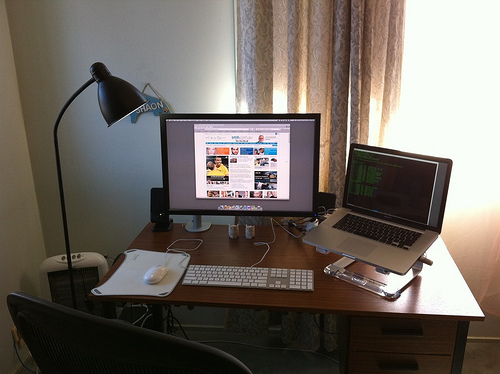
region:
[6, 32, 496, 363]
a computer workspace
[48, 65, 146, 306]
a tall black lamp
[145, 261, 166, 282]
a white mouse on the mousepad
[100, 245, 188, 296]
a white mousepad and a mouse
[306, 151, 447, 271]
an apple laptop on a base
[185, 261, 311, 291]
the keyboard is white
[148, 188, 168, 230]
computer speaker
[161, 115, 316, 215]
a computer monitor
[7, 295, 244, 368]
a black chair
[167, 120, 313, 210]
the monitor display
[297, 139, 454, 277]
the laptop computer is turned on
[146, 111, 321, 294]
the desktop computer is turned on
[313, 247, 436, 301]
the laptop computer is on a way-cool stand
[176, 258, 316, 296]
the keyboard of the desktop computer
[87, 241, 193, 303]
the mouse pad for the desktop computer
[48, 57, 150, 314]
a lamp set up next to the desk for more light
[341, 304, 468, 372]
this desk has a couple of drawers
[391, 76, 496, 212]
sunlight shines in from the window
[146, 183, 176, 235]
a speaker for the desktop computer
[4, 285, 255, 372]
the chair used by the owner of these computers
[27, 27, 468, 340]
Two computers sitting on a desk.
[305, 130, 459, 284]
A laptop computer that's open.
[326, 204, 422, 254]
Keyboard on a laptop.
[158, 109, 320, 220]
A computer monitor.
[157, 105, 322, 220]
Computer monitor is on.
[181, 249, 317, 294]
Keyboard for computer.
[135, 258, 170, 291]
A white mouse for computer.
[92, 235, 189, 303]
A large mousepad.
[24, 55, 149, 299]
A black floor lamp.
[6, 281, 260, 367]
The back of a computer chair.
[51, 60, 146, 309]
black lamp with floor stand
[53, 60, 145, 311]
lamp shining on a desk from above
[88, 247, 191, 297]
large white mouse pad on a desk next to a keyboard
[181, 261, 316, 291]
very thin modern style computer keyboard found on a desk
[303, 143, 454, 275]
black and silver laptop sitting on top of a stand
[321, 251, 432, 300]
laptop stand sitting on a desk and raising a laptop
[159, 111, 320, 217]
computer monitor on a desk next to a laptop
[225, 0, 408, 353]
long neutral colored curtain partially covering a window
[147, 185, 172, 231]
small black computer speaker sitting next to a monitor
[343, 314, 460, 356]
top drawer on a desk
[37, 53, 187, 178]
the lamp is black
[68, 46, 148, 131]
the lamp is black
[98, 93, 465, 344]
computer on a desk